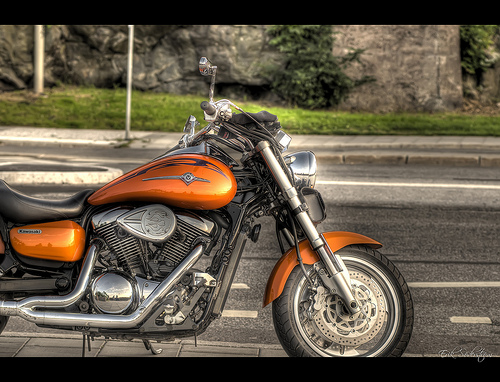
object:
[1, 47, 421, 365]
motorcycle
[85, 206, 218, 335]
engine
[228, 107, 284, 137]
gloves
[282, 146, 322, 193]
headlights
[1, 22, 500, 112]
wall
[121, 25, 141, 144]
pole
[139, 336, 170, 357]
kickstand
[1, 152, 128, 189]
island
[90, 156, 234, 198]
marks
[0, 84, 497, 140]
grass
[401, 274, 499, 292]
line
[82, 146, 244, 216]
tank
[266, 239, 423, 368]
wheel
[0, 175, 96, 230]
seat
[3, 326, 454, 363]
sidewalk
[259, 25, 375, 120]
tree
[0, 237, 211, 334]
pipes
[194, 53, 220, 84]
mirror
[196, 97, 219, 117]
handlebar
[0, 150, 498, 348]
street